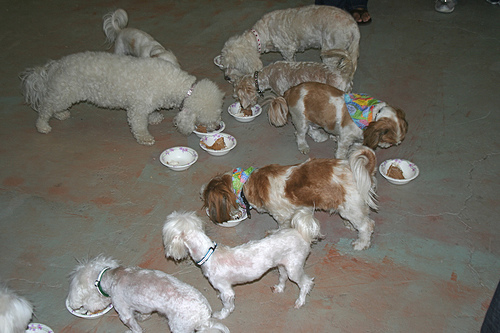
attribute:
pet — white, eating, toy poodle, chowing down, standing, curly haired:
[20, 49, 224, 147]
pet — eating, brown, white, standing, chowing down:
[196, 146, 379, 252]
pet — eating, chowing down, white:
[62, 256, 230, 333]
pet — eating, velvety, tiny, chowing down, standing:
[231, 46, 354, 115]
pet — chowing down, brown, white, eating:
[268, 78, 409, 163]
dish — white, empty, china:
[157, 144, 201, 173]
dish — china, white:
[200, 132, 236, 157]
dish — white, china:
[380, 157, 419, 185]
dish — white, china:
[227, 99, 264, 123]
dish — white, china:
[189, 118, 227, 139]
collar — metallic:
[176, 78, 200, 113]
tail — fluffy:
[21, 59, 56, 112]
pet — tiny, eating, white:
[100, 7, 179, 68]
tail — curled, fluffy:
[99, 7, 128, 42]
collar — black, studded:
[253, 69, 264, 98]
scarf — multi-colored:
[340, 91, 389, 131]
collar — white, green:
[96, 264, 114, 300]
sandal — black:
[350, 7, 372, 25]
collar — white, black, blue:
[195, 239, 217, 268]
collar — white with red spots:
[247, 26, 266, 55]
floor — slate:
[1, 2, 498, 332]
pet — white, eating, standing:
[218, 6, 361, 85]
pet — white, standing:
[159, 210, 327, 318]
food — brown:
[208, 137, 225, 150]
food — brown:
[385, 163, 406, 177]